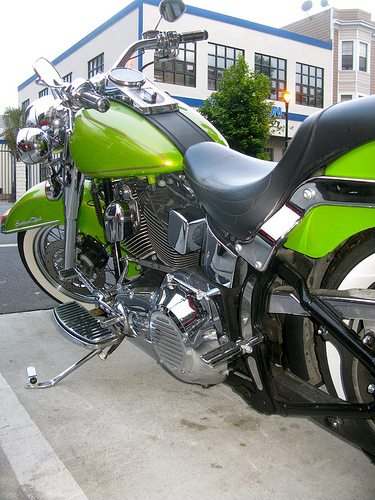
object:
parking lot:
[0, 198, 374, 497]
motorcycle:
[0, 0, 375, 463]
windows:
[203, 39, 246, 96]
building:
[0, 0, 375, 203]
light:
[282, 91, 292, 104]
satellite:
[302, 0, 314, 19]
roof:
[271, 4, 373, 27]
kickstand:
[24, 332, 125, 390]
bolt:
[26, 364, 39, 388]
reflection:
[167, 293, 196, 321]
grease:
[223, 408, 258, 434]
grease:
[174, 416, 209, 432]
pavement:
[0, 282, 371, 500]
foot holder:
[200, 331, 265, 365]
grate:
[148, 312, 229, 386]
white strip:
[2, 370, 89, 498]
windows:
[295, 59, 325, 106]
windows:
[251, 50, 286, 101]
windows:
[151, 32, 197, 85]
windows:
[84, 48, 106, 79]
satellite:
[321, 1, 330, 9]